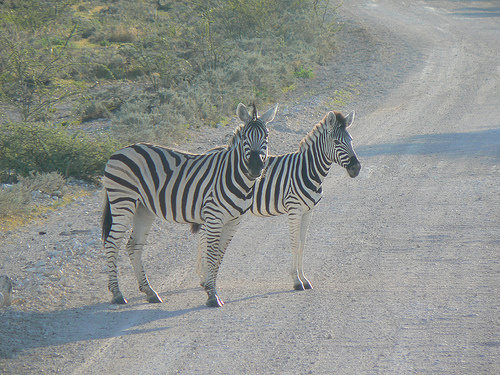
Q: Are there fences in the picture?
A: No, there are no fences.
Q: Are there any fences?
A: No, there are no fences.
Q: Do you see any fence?
A: No, there are no fences.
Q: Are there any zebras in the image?
A: Yes, there is a zebra.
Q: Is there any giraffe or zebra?
A: Yes, there is a zebra.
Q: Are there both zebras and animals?
A: Yes, there are both a zebra and animals.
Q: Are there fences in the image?
A: No, there are no fences.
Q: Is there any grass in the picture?
A: Yes, there is grass.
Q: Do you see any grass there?
A: Yes, there is grass.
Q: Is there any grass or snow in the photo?
A: Yes, there is grass.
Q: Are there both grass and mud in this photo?
A: No, there is grass but no mud.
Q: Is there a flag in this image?
A: No, there are no flags.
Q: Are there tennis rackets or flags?
A: No, there are no flags or tennis rackets.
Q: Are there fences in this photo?
A: No, there are no fences.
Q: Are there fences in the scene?
A: No, there are no fences.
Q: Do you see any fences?
A: No, there are no fences.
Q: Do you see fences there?
A: No, there are no fences.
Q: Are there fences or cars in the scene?
A: No, there are no fences or cars.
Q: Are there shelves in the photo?
A: No, there are no shelves.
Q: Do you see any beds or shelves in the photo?
A: No, there are no shelves or beds.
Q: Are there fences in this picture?
A: No, there are no fences.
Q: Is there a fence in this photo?
A: No, there are no fences.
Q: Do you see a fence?
A: No, there are no fences.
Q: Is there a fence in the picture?
A: No, there are no fences.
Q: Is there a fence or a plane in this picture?
A: No, there are no fences or airplanes.